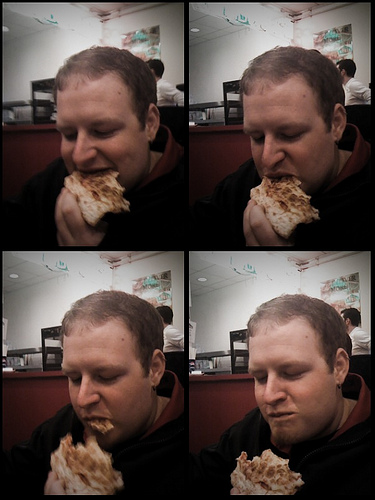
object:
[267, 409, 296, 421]
lips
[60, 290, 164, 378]
hair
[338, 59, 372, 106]
person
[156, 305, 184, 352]
person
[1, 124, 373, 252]
counter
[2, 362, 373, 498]
counter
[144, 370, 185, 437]
collar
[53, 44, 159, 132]
hair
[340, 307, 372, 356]
man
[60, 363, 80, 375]
eyebrow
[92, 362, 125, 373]
eyebrow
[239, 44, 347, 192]
head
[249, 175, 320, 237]
brown bread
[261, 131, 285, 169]
nose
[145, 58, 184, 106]
man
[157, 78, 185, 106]
shirt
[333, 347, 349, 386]
ear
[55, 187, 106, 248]
man`s hand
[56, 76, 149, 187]
face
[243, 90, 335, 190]
face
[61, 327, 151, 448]
face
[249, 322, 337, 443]
face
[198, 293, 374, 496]
man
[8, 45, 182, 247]
man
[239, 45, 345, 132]
hair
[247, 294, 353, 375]
hair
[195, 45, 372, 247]
man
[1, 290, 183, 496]
man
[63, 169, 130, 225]
food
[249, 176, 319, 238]
food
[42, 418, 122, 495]
food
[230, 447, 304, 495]
food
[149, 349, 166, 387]
ear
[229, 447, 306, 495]
bread